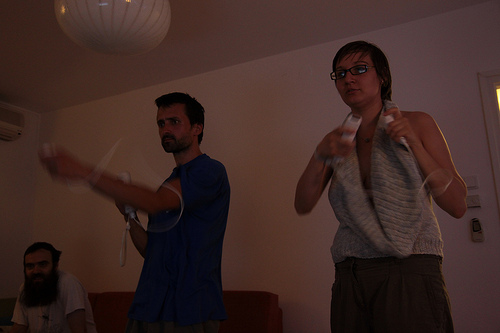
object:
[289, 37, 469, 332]
female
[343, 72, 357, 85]
nose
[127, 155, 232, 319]
blue shirt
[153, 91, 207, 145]
black hair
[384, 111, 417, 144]
hand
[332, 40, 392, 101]
hair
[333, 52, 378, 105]
face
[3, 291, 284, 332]
couch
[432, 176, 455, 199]
wire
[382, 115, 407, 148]
white controllers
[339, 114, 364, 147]
white controllers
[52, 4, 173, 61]
light fixture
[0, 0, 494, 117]
ceiling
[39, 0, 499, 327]
wall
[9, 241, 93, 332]
man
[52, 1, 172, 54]
object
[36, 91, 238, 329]
man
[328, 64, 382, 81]
glasses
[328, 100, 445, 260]
sweater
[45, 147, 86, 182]
hand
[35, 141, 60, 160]
controller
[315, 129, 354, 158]
right hand